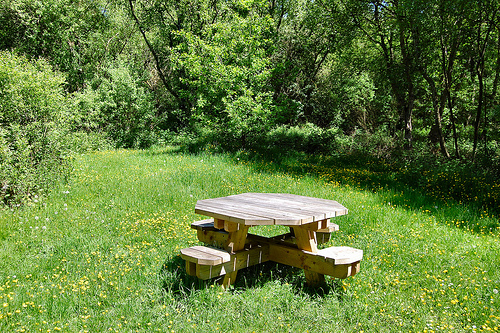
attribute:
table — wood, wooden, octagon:
[196, 191, 349, 246]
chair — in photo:
[181, 244, 231, 262]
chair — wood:
[192, 219, 215, 230]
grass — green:
[0, 142, 499, 333]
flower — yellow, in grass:
[424, 209, 429, 214]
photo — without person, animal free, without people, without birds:
[0, 0, 498, 333]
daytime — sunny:
[0, 2, 499, 332]